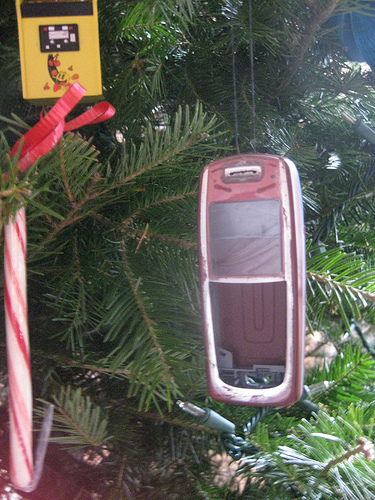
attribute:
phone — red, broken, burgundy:
[194, 158, 301, 412]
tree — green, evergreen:
[49, 132, 207, 394]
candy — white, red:
[1, 184, 48, 493]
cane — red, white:
[8, 199, 30, 485]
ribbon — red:
[11, 82, 111, 179]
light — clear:
[162, 387, 257, 450]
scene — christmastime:
[1, 2, 362, 489]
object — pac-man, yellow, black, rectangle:
[16, 0, 104, 101]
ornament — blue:
[327, 4, 374, 65]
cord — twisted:
[231, 404, 272, 468]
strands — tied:
[217, 1, 272, 159]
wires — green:
[225, 413, 293, 468]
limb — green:
[82, 119, 214, 172]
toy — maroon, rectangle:
[167, 139, 333, 420]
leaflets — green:
[106, 105, 186, 189]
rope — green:
[214, 9, 256, 141]